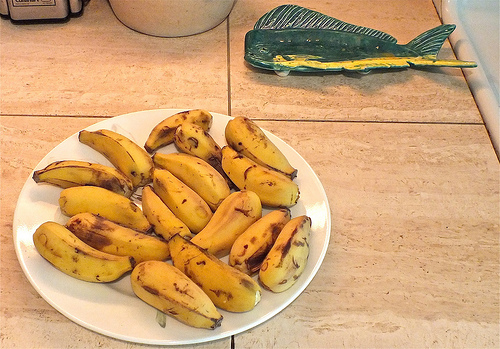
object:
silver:
[0, 0, 89, 21]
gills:
[269, 28, 349, 60]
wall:
[434, 0, 500, 164]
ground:
[0, 0, 499, 349]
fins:
[406, 24, 456, 60]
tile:
[226, 114, 498, 345]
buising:
[65, 214, 115, 251]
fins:
[254, 4, 397, 44]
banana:
[31, 109, 312, 330]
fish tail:
[406, 24, 477, 68]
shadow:
[243, 40, 488, 98]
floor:
[1, 0, 500, 349]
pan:
[107, 0, 233, 38]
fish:
[243, 4, 478, 77]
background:
[0, 0, 478, 77]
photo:
[0, 0, 499, 349]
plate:
[12, 108, 332, 346]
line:
[252, 119, 484, 125]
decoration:
[405, 24, 477, 68]